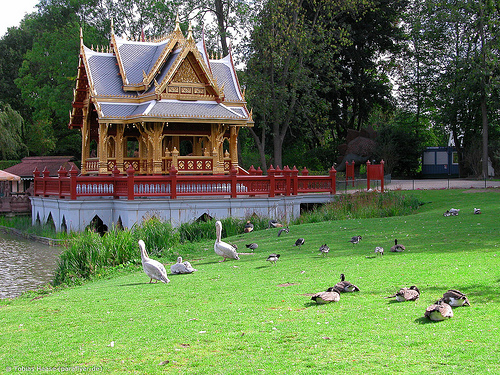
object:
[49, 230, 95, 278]
plants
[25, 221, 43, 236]
reeds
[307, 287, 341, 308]
duck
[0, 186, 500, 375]
grass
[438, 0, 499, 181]
water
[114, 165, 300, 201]
fence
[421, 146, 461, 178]
building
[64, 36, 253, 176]
house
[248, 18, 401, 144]
trees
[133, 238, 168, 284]
pelican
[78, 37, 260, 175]
gazebo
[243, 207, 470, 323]
birds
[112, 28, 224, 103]
roof